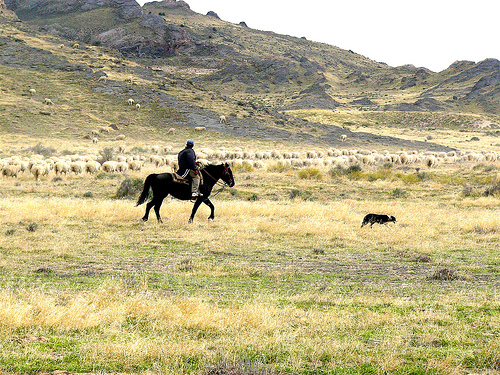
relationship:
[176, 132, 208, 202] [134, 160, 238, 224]
man on horse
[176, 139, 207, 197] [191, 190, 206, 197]
man wearing shoes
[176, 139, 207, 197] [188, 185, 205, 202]
man wearing shoes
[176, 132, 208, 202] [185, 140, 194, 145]
man wearing hat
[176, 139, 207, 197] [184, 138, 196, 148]
man wearing hat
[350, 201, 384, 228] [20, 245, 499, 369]
dog walking on grass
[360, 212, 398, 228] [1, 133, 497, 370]
dog walking on grass